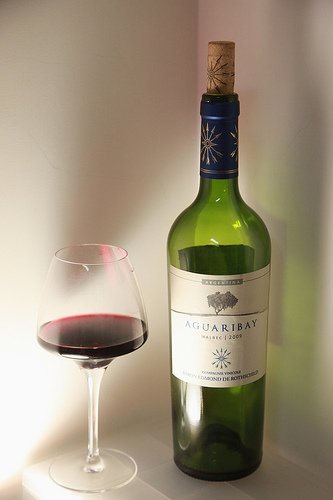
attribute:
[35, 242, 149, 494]
empty glass — almost empty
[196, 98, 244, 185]
label — blue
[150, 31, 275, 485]
wine — red, bottled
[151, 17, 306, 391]
glass — wine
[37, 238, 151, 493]
glass — wine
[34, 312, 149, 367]
wine — red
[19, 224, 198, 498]
glass — wine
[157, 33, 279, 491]
bottle — bright, green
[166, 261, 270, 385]
lable — blue, white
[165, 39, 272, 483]
bottle — glass, green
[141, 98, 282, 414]
bottle — wine 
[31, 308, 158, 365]
wine — red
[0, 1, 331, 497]
background — white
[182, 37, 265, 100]
cork — wine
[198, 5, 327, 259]
wall — plain, white